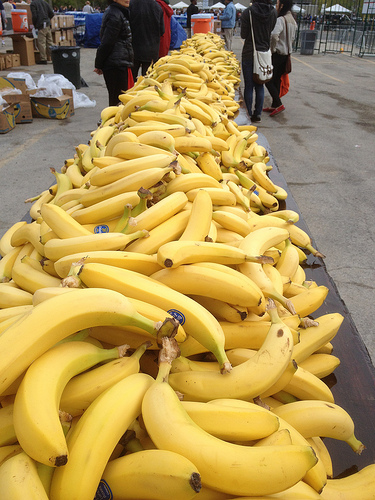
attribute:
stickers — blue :
[85, 222, 112, 233]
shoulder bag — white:
[244, 12, 282, 85]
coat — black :
[91, 10, 137, 78]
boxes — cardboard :
[5, 15, 80, 134]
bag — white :
[248, 10, 275, 86]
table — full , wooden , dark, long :
[15, 37, 372, 497]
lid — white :
[10, 8, 26, 12]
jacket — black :
[92, 1, 135, 74]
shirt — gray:
[270, 12, 295, 57]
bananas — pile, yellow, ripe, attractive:
[42, 26, 315, 384]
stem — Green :
[261, 304, 286, 319]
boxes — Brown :
[1, 66, 80, 129]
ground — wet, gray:
[295, 49, 370, 365]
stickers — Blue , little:
[94, 222, 114, 232]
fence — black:
[297, 3, 370, 64]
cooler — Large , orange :
[188, 15, 213, 35]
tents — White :
[170, 2, 246, 14]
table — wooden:
[230, 89, 253, 127]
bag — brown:
[248, 47, 280, 81]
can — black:
[48, 43, 90, 94]